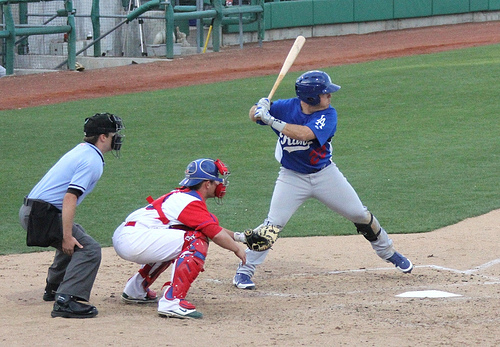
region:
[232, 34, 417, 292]
baseball batter with bat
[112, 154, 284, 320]
catcher crouching in the dirt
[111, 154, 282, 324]
catcher with leather glove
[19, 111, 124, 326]
bend over empire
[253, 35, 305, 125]
wooden baseball bat in hands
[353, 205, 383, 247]
kneepad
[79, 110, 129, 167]
hat and protective face mask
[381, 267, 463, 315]
diamond in the dirt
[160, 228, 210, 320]
red shin guard on a leg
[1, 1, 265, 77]
green metal fencing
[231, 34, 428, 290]
A batter getting ready to swing at a ball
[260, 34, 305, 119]
A wood baseball bat in the batter's hands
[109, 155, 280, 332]
The catcher crouched behind the plate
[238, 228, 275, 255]
The catcher's leather mitt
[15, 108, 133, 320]
The umpire crouching behind the catcher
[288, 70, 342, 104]
The batter's shiny blue batting helmet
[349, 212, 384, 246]
The batter's black shin guard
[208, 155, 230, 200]
The catcher's red face mask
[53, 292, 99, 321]
The umpire's black right shoe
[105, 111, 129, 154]
The umpire's black metal face mask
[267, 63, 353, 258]
Man swinging a baseball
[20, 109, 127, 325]
Umpire watching baseball pitch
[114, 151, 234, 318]
Shortstop preparing to catch baseball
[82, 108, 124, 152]
Umpire wearing black face guard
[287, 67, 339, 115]
Man wearing blue baseball helmet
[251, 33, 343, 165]
Man holding baseball bat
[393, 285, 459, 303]
Home plate of baseball diamond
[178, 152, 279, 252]
Man wearing catcher's mitt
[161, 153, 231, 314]
Man wearing red shin guards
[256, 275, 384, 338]
Loose brown soil on baseball diamond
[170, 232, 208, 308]
a man wearing leg gaurds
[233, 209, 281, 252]
a black and white baseball glove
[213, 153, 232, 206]
a man wearing a face mask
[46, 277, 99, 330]
a black pair of shoes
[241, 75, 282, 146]
a pair of batting gloves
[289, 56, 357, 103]
a man wearing a baseball helmet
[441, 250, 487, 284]
white lin painted on the field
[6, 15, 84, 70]
a fence between the dugout and field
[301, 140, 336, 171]
a number on the players shirt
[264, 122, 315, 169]
the teams name on the shirt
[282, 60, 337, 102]
Person wearing blue helmet.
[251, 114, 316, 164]
Person wearing blue shirt.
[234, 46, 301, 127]
Person holding baseball bat.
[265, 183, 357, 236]
Person wearing gray pants.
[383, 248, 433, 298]
Person wearing blue and white shoes.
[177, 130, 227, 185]
Person wearing blue helmet.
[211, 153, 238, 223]
Person wearing red mask.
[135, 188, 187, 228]
Person wearing red and white shirt.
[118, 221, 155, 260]
Person wearing white pants.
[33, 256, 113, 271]
Person wearing gray pants.